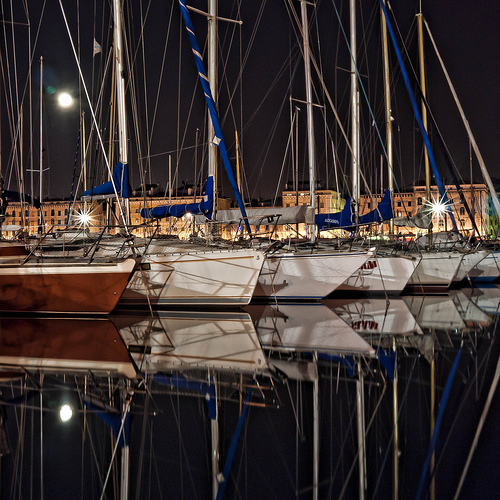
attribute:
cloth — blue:
[149, 201, 212, 220]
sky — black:
[1, 0, 498, 200]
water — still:
[26, 249, 478, 483]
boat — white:
[63, 0, 276, 310]